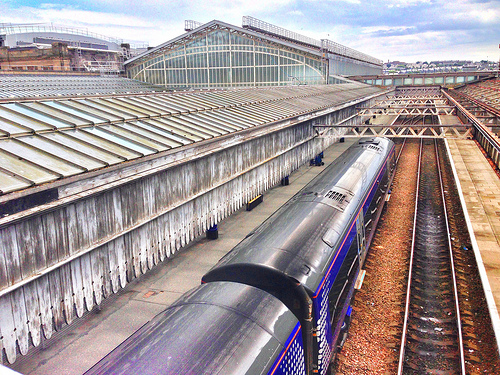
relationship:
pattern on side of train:
[302, 297, 349, 374] [200, 134, 390, 371]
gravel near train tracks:
[331, 115, 425, 374] [326, 100, 497, 373]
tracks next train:
[399, 258, 466, 358] [141, 131, 396, 373]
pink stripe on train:
[273, 232, 358, 374] [73, 121, 403, 373]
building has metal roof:
[1, 60, 358, 338] [63, 100, 147, 148]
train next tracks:
[108, 128, 398, 373] [387, 122, 467, 374]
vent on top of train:
[319, 185, 348, 204] [249, 131, 403, 335]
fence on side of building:
[1, 87, 398, 372] [2, 67, 394, 362]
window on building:
[149, 36, 306, 82] [124, 10, 382, 89]